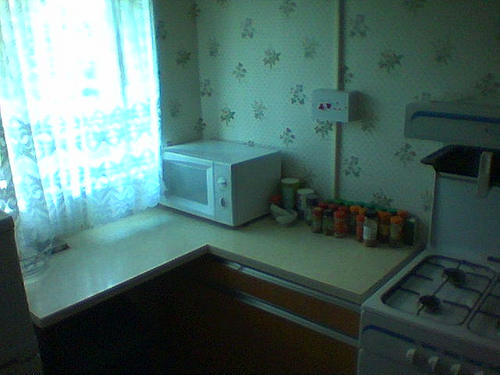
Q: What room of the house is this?
A: The kitchen.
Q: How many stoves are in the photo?
A: 1.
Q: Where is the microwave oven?
A: On the counter.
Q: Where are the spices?
A: On the counter.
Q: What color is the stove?
A: White.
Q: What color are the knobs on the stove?
A: White.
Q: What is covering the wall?
A: Wallpaper.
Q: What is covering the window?
A: A curtain.